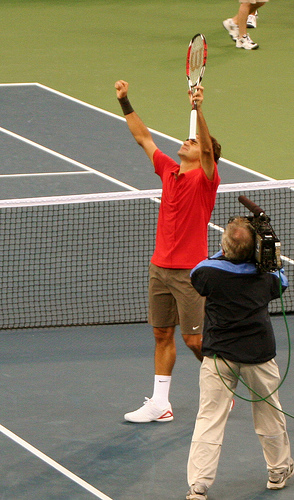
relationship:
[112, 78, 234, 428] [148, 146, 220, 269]
man wearing shirt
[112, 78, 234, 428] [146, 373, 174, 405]
man wearing sock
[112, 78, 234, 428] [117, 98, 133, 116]
man wearing wrist band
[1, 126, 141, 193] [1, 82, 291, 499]
line on tennis pitch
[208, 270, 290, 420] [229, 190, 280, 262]
wire connecting video camera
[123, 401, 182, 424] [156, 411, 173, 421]
shoe has design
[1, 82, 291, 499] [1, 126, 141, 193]
tennis pitch has line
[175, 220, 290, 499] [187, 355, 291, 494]
camera man has pants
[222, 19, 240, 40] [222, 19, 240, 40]
sneaker on sneaker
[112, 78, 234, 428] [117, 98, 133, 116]
man has wrist band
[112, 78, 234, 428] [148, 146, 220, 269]
man has shirt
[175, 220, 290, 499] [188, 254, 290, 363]
camera man has shirt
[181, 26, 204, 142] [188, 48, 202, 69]
tennis racket has w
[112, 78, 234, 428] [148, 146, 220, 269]
man wears shirt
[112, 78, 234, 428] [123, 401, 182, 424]
man wears shoe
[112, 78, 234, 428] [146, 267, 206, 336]
man wears shorts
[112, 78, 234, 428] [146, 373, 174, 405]
man has sock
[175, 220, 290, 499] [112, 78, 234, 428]
camera man filming man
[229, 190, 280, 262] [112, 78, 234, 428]
video camera pointing on man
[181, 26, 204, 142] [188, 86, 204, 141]
tennis racket has handle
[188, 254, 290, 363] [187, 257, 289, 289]
shirt has stripe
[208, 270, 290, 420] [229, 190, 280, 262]
wire attached to video camera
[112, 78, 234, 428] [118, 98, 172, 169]
man has arm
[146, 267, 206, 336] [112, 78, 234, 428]
shorts on man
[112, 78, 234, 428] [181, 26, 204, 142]
man holding tennis racket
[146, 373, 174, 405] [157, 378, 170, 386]
sock has logo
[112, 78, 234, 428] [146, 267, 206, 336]
man has shorts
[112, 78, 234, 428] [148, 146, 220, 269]
man in shirt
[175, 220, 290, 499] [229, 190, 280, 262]
camera man has video camera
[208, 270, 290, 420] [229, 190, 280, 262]
wire connecting to video camera